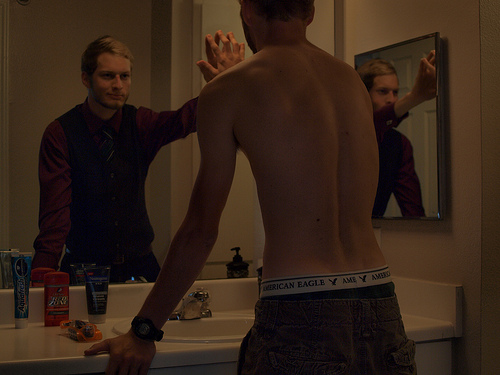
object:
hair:
[80, 35, 135, 75]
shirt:
[32, 96, 198, 269]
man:
[31, 33, 198, 283]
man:
[356, 49, 438, 220]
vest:
[54, 103, 155, 260]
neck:
[254, 26, 307, 51]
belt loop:
[361, 301, 371, 341]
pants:
[58, 250, 160, 284]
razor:
[57, 319, 102, 341]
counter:
[0, 275, 462, 375]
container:
[44, 271, 69, 326]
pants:
[233, 297, 419, 374]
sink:
[111, 313, 254, 343]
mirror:
[0, 0, 266, 290]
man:
[83, 0, 419, 375]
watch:
[129, 315, 164, 341]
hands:
[198, 30, 244, 74]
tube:
[0, 248, 20, 290]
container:
[84, 267, 112, 324]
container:
[10, 257, 33, 330]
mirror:
[353, 31, 442, 219]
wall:
[342, 1, 481, 331]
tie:
[102, 125, 116, 161]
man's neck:
[85, 94, 117, 121]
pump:
[231, 247, 241, 255]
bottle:
[225, 247, 249, 278]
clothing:
[238, 266, 418, 375]